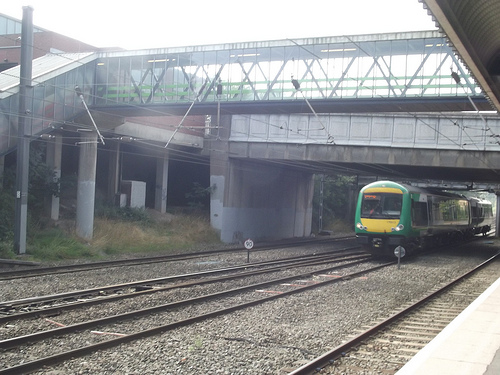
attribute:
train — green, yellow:
[350, 177, 496, 253]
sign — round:
[243, 237, 256, 264]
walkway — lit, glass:
[96, 50, 462, 108]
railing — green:
[93, 72, 485, 101]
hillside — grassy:
[96, 198, 212, 251]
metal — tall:
[8, 3, 37, 258]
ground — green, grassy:
[29, 227, 77, 261]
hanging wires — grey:
[1, 109, 499, 180]